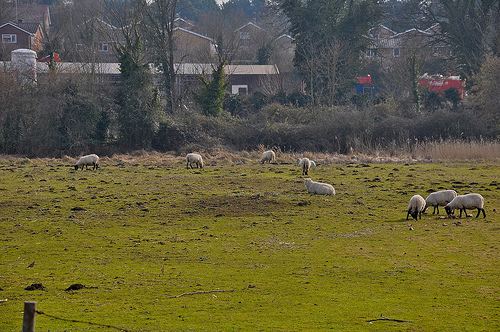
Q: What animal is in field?
A: Grassy field.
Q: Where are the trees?
A: In background.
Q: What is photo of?
A: Animals in field.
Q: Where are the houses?
A: Behind trees.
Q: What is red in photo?
A: House.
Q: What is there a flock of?
A: Sheeps.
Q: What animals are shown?
A: Sheep.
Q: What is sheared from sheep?
A: Wool.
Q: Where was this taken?
A: A farm.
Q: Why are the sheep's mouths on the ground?
A: They are grazing.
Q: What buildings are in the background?
A: Houses.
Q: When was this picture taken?
A: During the day.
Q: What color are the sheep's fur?
A: White.